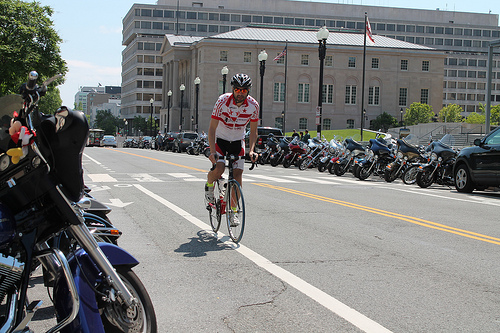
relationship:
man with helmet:
[201, 67, 262, 231] [225, 70, 255, 88]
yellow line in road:
[106, 144, 499, 246] [80, 145, 499, 330]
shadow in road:
[172, 228, 242, 258] [80, 145, 499, 330]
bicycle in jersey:
[205, 152, 257, 243] [211, 91, 259, 141]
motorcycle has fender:
[0, 71, 157, 333] [66, 234, 136, 314]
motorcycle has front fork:
[0, 71, 157, 333] [59, 187, 158, 327]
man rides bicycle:
[205, 73, 260, 226] [200, 140, 260, 246]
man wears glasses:
[205, 73, 260, 226] [234, 87, 250, 94]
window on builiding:
[392, 83, 419, 115] [162, 20, 467, 152]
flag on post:
[363, 13, 377, 43] [359, 10, 367, 140]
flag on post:
[271, 43, 287, 60] [281, 38, 288, 135]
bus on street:
[86, 124, 104, 144] [80, 131, 498, 331]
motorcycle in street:
[2, 72, 157, 330] [76, 147, 498, 327]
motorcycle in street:
[123, 127, 459, 190] [76, 147, 498, 327]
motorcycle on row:
[123, 127, 459, 190] [105, 119, 495, 192]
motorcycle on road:
[123, 127, 459, 190] [80, 145, 499, 330]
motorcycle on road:
[123, 127, 459, 190] [89, 123, 496, 330]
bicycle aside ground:
[204, 147, 258, 244] [353, 175, 386, 211]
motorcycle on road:
[265, 112, 482, 203] [153, 199, 482, 322]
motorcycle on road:
[2, 72, 157, 330] [80, 145, 499, 330]